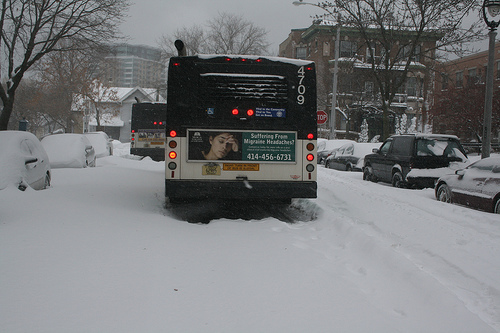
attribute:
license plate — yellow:
[221, 161, 260, 170]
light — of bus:
[163, 126, 176, 186]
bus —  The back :
[157, 34, 316, 231]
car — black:
[361, 120, 473, 202]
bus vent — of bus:
[195, 68, 293, 105]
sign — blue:
[253, 105, 288, 122]